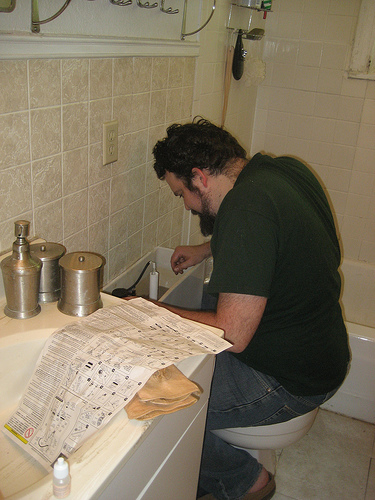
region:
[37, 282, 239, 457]
Extra Large Instruction Paper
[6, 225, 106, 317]
Silver Bathroom Containers On Sink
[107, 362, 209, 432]
Tan or Yellow Towel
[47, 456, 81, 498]
Plastic Bottle with Chemical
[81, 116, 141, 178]
Standard White Electric Outlet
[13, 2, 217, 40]
Wall Attached Silver Towel Hanger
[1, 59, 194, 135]
Clean White and Beige Tile Wall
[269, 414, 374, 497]
Clean Tile Floor With Grout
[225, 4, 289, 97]
Bathroom Shower Metal Accessories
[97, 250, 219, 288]
Uncovered Toilet Base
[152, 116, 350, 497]
Man repairing white toilet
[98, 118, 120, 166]
Electrical outlet in the wall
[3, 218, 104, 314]
Three stainless steel containers on the top of the sink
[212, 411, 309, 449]
White toilet man is sitting on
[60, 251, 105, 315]
Largest stainless steel container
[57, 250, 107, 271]
Top of stainless steel container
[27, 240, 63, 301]
Stainless steel container in the back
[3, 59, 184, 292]
Beige colored wall tile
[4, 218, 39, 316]
Long round stainless steel container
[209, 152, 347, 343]
Black shirt man is wearing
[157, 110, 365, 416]
man in black shirt sitting on toilet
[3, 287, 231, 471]
Instructions on sink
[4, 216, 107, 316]
silver pump on sink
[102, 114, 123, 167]
plugin on wall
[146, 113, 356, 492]
man in jeans and black shirt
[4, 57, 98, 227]
tiles on wall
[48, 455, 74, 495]
bottle with white top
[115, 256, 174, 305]
inside of toilet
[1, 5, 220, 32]
bathroom wall fixture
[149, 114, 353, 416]
man with black beard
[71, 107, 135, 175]
a white power outlet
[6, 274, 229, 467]
a white paper with instructions on it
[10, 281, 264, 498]
a white sink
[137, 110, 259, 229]
a man with facial hair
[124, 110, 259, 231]
a man with brown hair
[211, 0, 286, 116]
a shower caddy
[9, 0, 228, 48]
silver metal hooks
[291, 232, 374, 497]
a white bath tub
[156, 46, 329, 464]
a man wearing blue jeans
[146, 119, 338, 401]
a man wearing a tshirt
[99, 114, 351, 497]
Man sitting backwards on a toilet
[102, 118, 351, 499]
Man fixing the toilet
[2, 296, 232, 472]
White sheet of instructions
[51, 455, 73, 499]
Plastic dropper with white cap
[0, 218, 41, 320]
Dirty metal soap dispenser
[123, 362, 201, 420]
Pair of tan work gloves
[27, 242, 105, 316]
Two metal containers with lids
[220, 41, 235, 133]
Wood handle of a back scrubber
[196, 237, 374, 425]
White bath tub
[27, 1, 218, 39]
metal shelf and hangers